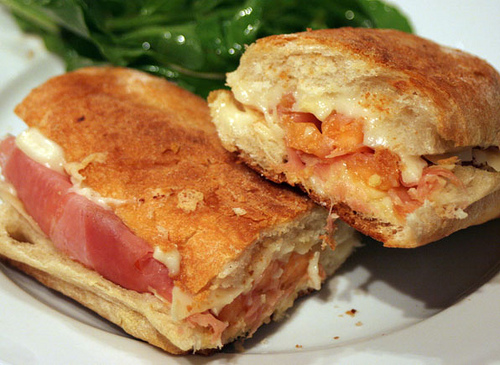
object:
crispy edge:
[321, 195, 411, 247]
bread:
[207, 28, 500, 249]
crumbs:
[296, 344, 303, 348]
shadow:
[326, 212, 499, 310]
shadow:
[169, 342, 247, 365]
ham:
[0, 135, 172, 303]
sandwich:
[206, 27, 500, 248]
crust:
[14, 65, 319, 294]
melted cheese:
[80, 188, 127, 215]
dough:
[237, 40, 440, 133]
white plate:
[1, 48, 497, 354]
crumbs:
[333, 336, 339, 340]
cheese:
[286, 87, 428, 188]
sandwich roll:
[0, 67, 366, 357]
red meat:
[183, 250, 309, 342]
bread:
[0, 66, 365, 356]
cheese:
[151, 240, 184, 279]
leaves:
[0, 0, 415, 99]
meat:
[0, 133, 173, 304]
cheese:
[12, 127, 86, 183]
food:
[111, 110, 230, 327]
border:
[327, 277, 404, 324]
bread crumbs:
[344, 308, 363, 327]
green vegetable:
[0, 0, 413, 99]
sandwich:
[1, 65, 363, 357]